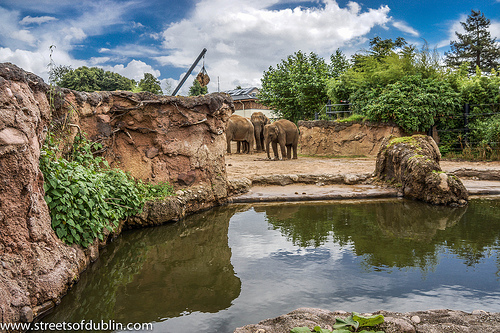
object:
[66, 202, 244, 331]
reflection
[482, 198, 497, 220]
water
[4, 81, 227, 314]
cliff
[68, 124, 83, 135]
vine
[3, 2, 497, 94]
sky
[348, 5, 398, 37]
cloud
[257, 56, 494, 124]
foliage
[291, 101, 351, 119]
fence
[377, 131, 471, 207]
rock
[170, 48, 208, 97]
pole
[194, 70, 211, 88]
bag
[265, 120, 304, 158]
elephant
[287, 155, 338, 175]
dirt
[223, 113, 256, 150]
elephant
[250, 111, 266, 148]
elephant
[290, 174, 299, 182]
boulder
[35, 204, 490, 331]
pool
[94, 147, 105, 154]
bush vine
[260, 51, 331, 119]
tree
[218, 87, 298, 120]
structure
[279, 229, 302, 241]
water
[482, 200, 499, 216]
water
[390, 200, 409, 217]
water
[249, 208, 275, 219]
water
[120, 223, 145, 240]
water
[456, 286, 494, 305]
water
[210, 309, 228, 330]
water